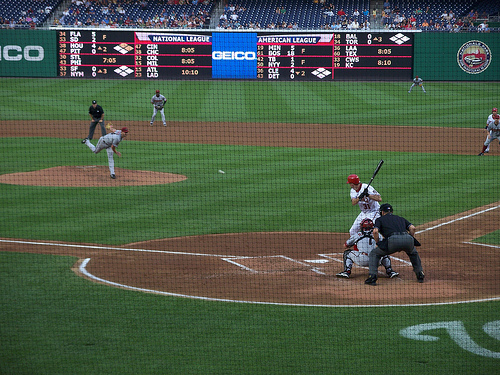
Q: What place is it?
A: It is a field.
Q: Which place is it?
A: It is a field.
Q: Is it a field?
A: Yes, it is a field.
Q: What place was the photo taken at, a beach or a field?
A: It was taken at a field.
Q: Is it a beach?
A: No, it is a field.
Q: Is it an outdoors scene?
A: Yes, it is outdoors.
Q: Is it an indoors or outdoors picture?
A: It is outdoors.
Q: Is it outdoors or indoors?
A: It is outdoors.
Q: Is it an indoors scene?
A: No, it is outdoors.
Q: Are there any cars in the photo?
A: No, there are no cars.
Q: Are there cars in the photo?
A: No, there are no cars.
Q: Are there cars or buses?
A: No, there are no cars or buses.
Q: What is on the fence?
A: The sign is on the fence.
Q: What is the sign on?
A: The sign is on the fence.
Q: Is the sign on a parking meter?
A: No, the sign is on the fence.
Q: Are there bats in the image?
A: Yes, there is a bat.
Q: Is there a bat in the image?
A: Yes, there is a bat.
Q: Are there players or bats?
A: Yes, there is a bat.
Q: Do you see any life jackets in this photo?
A: No, there are no life jackets.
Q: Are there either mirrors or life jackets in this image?
A: No, there are no life jackets or mirrors.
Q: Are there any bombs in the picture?
A: No, there are no bombs.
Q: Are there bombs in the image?
A: No, there are no bombs.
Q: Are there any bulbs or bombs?
A: No, there are no bombs or bulbs.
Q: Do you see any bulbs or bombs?
A: No, there are no bombs or bulbs.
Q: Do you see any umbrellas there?
A: No, there are no umbrellas.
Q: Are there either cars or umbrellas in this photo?
A: No, there are no umbrellas or cars.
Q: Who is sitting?
A: The people are sitting.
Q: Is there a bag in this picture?
A: No, there are no bags.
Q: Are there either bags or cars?
A: No, there are no bags or cars.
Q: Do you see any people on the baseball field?
A: Yes, there is a person on the field.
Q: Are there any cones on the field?
A: No, there is a person on the field.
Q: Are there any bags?
A: No, there are no bags.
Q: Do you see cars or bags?
A: No, there are no bags or cars.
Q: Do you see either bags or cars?
A: No, there are no bags or cars.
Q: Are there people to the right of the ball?
A: Yes, there is a person to the right of the ball.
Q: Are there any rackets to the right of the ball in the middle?
A: No, there is a person to the right of the ball.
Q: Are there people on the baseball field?
A: Yes, there is a person on the field.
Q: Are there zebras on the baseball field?
A: No, there is a person on the field.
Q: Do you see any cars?
A: No, there are no cars.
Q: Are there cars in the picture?
A: No, there are no cars.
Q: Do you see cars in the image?
A: No, there are no cars.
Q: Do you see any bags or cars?
A: No, there are no cars or bags.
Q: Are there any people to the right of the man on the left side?
A: Yes, there is a person to the right of the man.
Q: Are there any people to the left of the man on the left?
A: No, the person is to the right of the man.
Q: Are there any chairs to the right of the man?
A: No, there is a person to the right of the man.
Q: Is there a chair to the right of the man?
A: No, there is a person to the right of the man.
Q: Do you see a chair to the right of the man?
A: No, there is a person to the right of the man.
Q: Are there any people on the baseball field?
A: Yes, there is a person on the field.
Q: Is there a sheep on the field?
A: No, there is a person on the field.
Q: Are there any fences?
A: Yes, there is a fence.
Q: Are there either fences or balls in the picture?
A: Yes, there is a fence.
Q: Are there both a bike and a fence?
A: No, there is a fence but no bikes.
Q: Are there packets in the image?
A: No, there are no packets.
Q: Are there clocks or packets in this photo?
A: No, there are no packets or clocks.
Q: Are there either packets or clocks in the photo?
A: No, there are no packets or clocks.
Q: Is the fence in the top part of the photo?
A: Yes, the fence is in the top of the image.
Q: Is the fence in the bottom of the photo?
A: No, the fence is in the top of the image.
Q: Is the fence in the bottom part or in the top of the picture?
A: The fence is in the top of the image.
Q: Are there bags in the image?
A: No, there are no bags.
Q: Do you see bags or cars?
A: No, there are no bags or cars.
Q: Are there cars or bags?
A: No, there are no bags or cars.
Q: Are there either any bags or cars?
A: No, there are no bags or cars.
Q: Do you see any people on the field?
A: Yes, there is a person on the field.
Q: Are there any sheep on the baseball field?
A: No, there is a person on the field.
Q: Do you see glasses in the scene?
A: No, there are no glasses.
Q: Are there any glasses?
A: No, there are no glasses.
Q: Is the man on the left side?
A: Yes, the man is on the left of the image.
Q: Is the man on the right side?
A: No, the man is on the left of the image.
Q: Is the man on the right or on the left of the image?
A: The man is on the left of the image.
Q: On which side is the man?
A: The man is on the left of the image.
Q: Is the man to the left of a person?
A: Yes, the man is to the left of a person.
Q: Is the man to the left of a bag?
A: No, the man is to the left of a person.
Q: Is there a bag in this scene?
A: No, there are no bags.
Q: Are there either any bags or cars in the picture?
A: No, there are no bags or cars.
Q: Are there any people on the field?
A: Yes, there is a person on the field.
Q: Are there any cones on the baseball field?
A: No, there is a person on the field.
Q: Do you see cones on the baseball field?
A: No, there is a person on the field.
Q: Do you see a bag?
A: No, there are no bags.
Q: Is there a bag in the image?
A: No, there are no bags.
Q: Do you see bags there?
A: No, there are no bags.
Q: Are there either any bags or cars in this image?
A: No, there are no bags or cars.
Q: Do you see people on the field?
A: Yes, there is a person on the field.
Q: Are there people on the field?
A: Yes, there is a person on the field.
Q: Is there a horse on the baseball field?
A: No, there is a person on the field.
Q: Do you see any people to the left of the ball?
A: Yes, there is a person to the left of the ball.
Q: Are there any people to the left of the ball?
A: Yes, there is a person to the left of the ball.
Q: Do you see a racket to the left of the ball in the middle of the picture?
A: No, there is a person to the left of the ball.